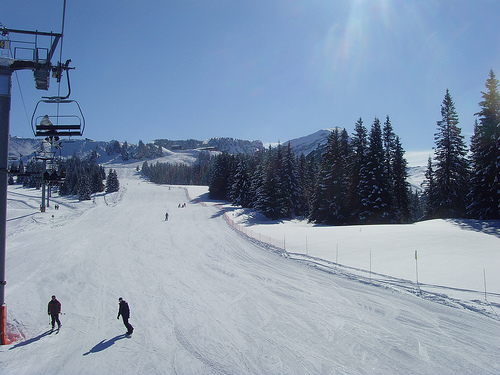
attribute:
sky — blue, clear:
[78, 6, 444, 113]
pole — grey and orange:
[0, 64, 23, 350]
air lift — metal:
[27, 96, 90, 145]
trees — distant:
[59, 152, 118, 201]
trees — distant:
[113, 138, 164, 160]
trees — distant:
[203, 136, 260, 152]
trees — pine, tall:
[200, 133, 428, 233]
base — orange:
[1, 301, 6, 347]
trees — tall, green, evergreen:
[359, 115, 398, 225]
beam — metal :
[0, 58, 19, 338]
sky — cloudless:
[8, 0, 499, 144]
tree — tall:
[429, 89, 466, 221]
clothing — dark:
[118, 301, 132, 333]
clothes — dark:
[117, 297, 134, 331]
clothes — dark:
[46, 299, 63, 327]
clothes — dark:
[162, 214, 171, 220]